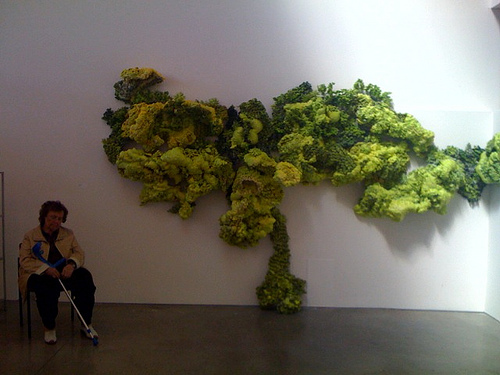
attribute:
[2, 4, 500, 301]
wall — green, grey, white, long, wide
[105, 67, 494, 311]
art — green, big, huge, massive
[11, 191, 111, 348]
woman — sitting, white, old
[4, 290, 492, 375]
floor — grey, dark